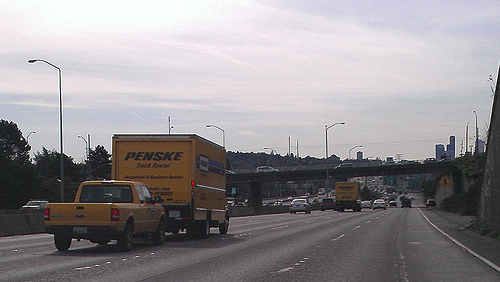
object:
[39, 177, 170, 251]
pickup truck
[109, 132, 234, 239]
truck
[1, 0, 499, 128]
clouds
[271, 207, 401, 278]
lane stripes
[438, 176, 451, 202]
sign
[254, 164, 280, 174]
car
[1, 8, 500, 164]
sky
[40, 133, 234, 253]
two trucks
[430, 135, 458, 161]
buildings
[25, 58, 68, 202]
street light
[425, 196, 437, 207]
car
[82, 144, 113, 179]
trees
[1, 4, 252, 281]
left side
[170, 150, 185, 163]
letters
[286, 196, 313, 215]
vehicles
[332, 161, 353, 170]
cars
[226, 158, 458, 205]
interstate bridge